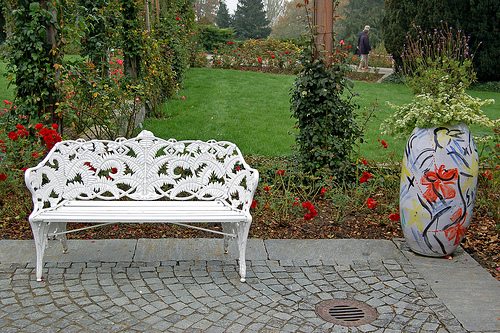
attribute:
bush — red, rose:
[2, 109, 86, 260]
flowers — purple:
[390, 19, 472, 88]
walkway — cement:
[345, 57, 391, 77]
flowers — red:
[366, 200, 377, 210]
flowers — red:
[304, 214, 310, 219]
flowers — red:
[318, 187, 326, 195]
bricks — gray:
[244, 297, 260, 307]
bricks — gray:
[149, 281, 165, 292]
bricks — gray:
[38, 302, 59, 312]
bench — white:
[23, 127, 261, 281]